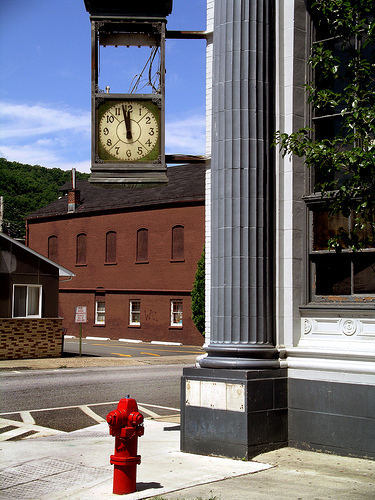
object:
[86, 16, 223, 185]
clock is mounted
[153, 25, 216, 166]
mounted from side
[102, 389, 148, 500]
red fire hydrant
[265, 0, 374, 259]
green foliage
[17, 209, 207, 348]
brown building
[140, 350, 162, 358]
yellow arrow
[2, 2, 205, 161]
blue sky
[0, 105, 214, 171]
sky with white cloud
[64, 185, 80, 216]
chimney of building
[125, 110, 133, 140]
black hands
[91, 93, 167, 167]
clock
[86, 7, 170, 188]
clock hanging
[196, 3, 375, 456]
building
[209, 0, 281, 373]
doric column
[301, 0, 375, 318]
window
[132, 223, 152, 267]
windows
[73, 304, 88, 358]
parking sign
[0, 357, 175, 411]
street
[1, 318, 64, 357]
brown bricks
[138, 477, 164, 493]
shadow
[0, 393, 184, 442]
white paint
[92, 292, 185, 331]
three windows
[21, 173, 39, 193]
lots of tree tops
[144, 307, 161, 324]
black graffit on wal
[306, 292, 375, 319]
grey windowsill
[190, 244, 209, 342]
tree on side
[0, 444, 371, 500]
portion of sidewalk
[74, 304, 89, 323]
white sign in lot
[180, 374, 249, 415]
section of base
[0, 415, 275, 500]
white barrier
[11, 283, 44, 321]
white window